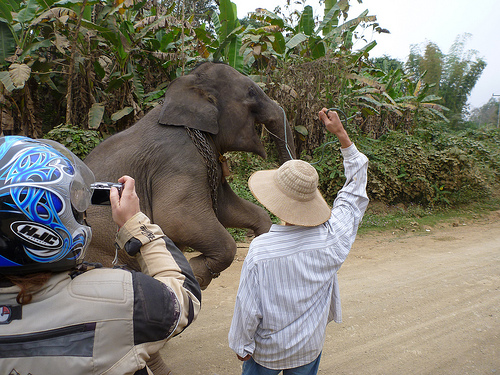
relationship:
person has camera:
[0, 133, 201, 373] [86, 177, 125, 208]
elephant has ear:
[85, 60, 297, 372] [155, 72, 220, 134]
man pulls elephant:
[212, 160, 385, 362] [38, 57, 313, 334]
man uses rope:
[212, 160, 385, 362] [277, 92, 352, 177]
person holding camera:
[0, 133, 201, 373] [86, 170, 126, 211]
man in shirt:
[235, 106, 370, 361] [226, 141, 369, 371]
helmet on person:
[0, 136, 95, 274] [0, 133, 201, 373]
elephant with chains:
[84, 61, 298, 291] [185, 126, 219, 216]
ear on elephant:
[161, 67, 218, 135] [69, 59, 305, 287]